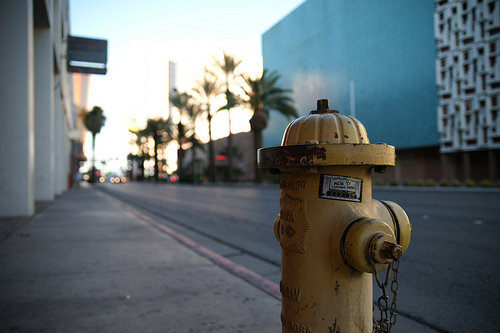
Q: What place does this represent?
A: It represents the road.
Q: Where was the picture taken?
A: It was taken at the road.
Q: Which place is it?
A: It is a road.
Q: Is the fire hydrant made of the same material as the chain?
A: Yes, both the fire hydrant and the chain are made of metal.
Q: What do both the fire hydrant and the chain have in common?
A: The material, both the fire hydrant and the chain are metallic.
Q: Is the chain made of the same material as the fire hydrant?
A: Yes, both the chain and the fire hydrant are made of metal.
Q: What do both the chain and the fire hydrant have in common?
A: The material, both the chain and the fire hydrant are metallic.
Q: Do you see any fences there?
A: No, there are no fences.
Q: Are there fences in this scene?
A: No, there are no fences.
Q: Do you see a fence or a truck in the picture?
A: No, there are no fences or trucks.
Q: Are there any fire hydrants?
A: Yes, there is a fire hydrant.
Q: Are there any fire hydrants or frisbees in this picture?
A: Yes, there is a fire hydrant.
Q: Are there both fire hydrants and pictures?
A: No, there is a fire hydrant but no pictures.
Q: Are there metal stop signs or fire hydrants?
A: Yes, there is a metal fire hydrant.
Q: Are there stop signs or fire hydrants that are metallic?
A: Yes, the fire hydrant is metallic.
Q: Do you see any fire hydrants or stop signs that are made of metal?
A: Yes, the fire hydrant is made of metal.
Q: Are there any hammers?
A: No, there are no hammers.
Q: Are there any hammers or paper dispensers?
A: No, there are no hammers or paper dispensers.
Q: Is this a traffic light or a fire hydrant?
A: This is a fire hydrant.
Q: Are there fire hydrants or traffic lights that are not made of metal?
A: No, there is a fire hydrant but it is made of metal.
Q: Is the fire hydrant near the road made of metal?
A: Yes, the fire hydrant is made of metal.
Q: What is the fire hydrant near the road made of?
A: The hydrant is made of metal.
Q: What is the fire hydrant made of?
A: The hydrant is made of metal.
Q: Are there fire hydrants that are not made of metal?
A: No, there is a fire hydrant but it is made of metal.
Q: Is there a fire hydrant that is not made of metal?
A: No, there is a fire hydrant but it is made of metal.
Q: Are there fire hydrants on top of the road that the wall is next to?
A: Yes, there is a fire hydrant on top of the road.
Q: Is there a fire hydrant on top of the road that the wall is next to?
A: Yes, there is a fire hydrant on top of the road.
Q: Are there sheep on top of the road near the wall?
A: No, there is a fire hydrant on top of the road.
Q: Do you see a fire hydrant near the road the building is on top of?
A: Yes, there is a fire hydrant near the road.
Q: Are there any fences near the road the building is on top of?
A: No, there is a fire hydrant near the road.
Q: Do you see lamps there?
A: No, there are no lamps.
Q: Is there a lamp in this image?
A: No, there are no lamps.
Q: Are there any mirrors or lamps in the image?
A: No, there are no lamps or mirrors.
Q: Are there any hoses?
A: No, there are no hoses.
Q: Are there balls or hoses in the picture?
A: No, there are no hoses or balls.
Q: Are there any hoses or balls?
A: No, there are no hoses or balls.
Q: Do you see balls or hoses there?
A: No, there are no hoses or balls.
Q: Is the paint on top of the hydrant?
A: Yes, the paint is on top of the hydrant.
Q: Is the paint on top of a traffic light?
A: No, the paint is on top of the hydrant.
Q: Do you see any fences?
A: No, there are no fences.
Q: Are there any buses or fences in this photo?
A: No, there are no fences or buses.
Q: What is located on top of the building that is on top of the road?
A: The sign is on top of the building.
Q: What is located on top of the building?
A: The sign is on top of the building.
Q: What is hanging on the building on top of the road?
A: The sign is hanging on the building.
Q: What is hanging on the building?
A: The sign is hanging on the building.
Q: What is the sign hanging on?
A: The sign is hanging on the building.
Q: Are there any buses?
A: No, there are no buses.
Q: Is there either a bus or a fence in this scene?
A: No, there are no buses or fences.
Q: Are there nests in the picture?
A: No, there are no nests.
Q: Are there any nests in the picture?
A: No, there are no nests.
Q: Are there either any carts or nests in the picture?
A: No, there are no nests or carts.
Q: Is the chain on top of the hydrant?
A: Yes, the chain is on top of the hydrant.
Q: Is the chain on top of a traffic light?
A: No, the chain is on top of the hydrant.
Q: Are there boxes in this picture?
A: No, there are no boxes.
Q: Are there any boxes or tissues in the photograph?
A: No, there are no boxes or tissues.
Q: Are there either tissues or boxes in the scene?
A: No, there are no boxes or tissues.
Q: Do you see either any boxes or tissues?
A: No, there are no boxes or tissues.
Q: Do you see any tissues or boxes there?
A: No, there are no boxes or tissues.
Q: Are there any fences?
A: No, there are no fences.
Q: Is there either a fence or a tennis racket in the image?
A: No, there are no fences or rackets.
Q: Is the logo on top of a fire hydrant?
A: Yes, the logo is on top of a fire hydrant.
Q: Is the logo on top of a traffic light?
A: No, the logo is on top of a fire hydrant.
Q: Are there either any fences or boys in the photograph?
A: No, there are no fences or boys.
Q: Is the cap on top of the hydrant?
A: Yes, the cap is on top of the hydrant.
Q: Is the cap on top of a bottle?
A: No, the cap is on top of the hydrant.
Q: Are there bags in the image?
A: No, there are no bags.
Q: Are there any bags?
A: No, there are no bags.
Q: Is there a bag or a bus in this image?
A: No, there are no bags or buses.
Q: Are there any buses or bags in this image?
A: No, there are no bags or buses.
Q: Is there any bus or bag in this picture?
A: No, there are no bags or buses.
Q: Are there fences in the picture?
A: No, there are no fences.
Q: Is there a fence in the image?
A: No, there are no fences.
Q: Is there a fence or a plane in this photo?
A: No, there are no fences or airplanes.